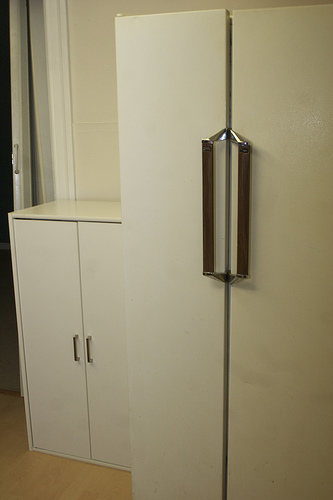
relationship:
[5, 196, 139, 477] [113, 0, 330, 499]
cabinet beside refrigerator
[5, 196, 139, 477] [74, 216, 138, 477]
cabinet has door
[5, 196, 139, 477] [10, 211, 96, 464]
cabinet has door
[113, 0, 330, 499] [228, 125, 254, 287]
refrigerator has handle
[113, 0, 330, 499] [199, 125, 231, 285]
refrigerator has handle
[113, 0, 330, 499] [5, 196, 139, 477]
refrigerator next to cabinet